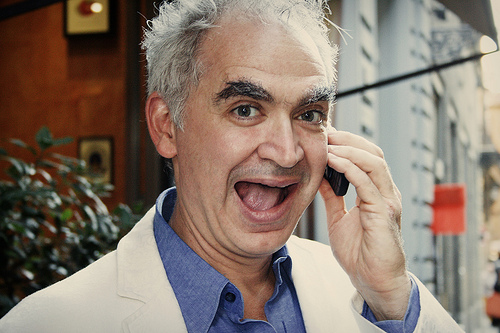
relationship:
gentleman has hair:
[0, 0, 467, 333] [141, 1, 352, 141]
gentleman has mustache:
[0, 0, 467, 333] [226, 163, 307, 183]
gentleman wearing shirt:
[0, 0, 467, 333] [160, 193, 308, 330]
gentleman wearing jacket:
[0, 0, 467, 333] [35, 231, 233, 323]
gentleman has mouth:
[0, 0, 467, 333] [226, 165, 308, 226]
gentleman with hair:
[0, 0, 467, 333] [136, 0, 353, 131]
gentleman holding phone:
[0, 0, 467, 333] [309, 148, 354, 199]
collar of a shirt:
[153, 230, 301, 325] [151, 183, 416, 328]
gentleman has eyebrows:
[0, 0, 467, 333] [213, 77, 335, 105]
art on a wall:
[77, 135, 111, 200] [33, 55, 66, 125]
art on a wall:
[62, 5, 109, 42] [33, 55, 66, 125]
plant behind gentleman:
[0, 122, 140, 306] [0, 0, 467, 333]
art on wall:
[77, 138, 111, 200] [3, 3, 149, 229]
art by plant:
[77, 138, 111, 200] [0, 122, 140, 306]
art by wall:
[77, 138, 111, 200] [3, 3, 149, 229]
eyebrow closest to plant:
[213, 75, 274, 107] [0, 122, 140, 306]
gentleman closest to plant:
[0, 0, 467, 333] [0, 122, 140, 306]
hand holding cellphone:
[318, 125, 410, 296] [323, 162, 349, 194]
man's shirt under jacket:
[153, 187, 309, 333] [4, 174, 474, 330]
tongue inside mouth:
[240, 183, 286, 210] [234, 165, 316, 240]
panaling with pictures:
[4, 2, 119, 278] [56, 2, 126, 198]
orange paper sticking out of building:
[406, 133, 478, 260] [312, 2, 485, 329]